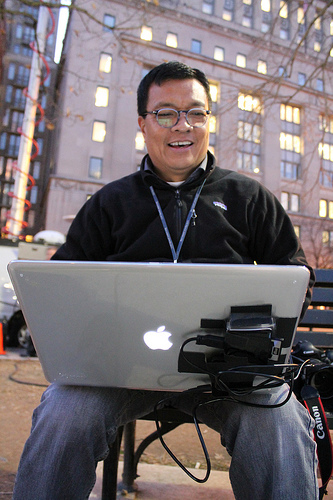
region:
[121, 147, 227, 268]
Blue lanyard in the neck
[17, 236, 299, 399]
Macbook on the man's lap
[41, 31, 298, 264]
A man wearing black fleece pullover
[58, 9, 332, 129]
Commercial building behind the man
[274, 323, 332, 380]
Canon Camara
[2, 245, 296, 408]
Apple laptop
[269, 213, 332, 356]
Black bench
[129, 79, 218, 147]
a man wearing prescription glasses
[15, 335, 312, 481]
A man wearing a blue jeans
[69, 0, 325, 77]
Leafless tree branches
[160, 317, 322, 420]
wires for man's computer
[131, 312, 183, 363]
computer makers logo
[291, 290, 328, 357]
bench man is sitting on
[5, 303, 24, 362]
car tire behind the man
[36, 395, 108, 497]
denim jean leg of man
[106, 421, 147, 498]
legs of the bench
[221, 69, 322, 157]
tree branches in background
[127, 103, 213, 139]
glasses on the man's face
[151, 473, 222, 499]
shadow on the ground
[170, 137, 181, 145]
gap in man's teeth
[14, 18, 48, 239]
red spiraled cord on antenna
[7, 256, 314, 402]
an Apple laptop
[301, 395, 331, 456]
a red and black camera strap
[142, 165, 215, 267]
a blue lanyard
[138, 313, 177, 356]
the Apple logo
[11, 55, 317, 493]
a man on a park bench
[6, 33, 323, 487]
a man outside on his computer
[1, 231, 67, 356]
a TV van parked behind the man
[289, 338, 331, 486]
camera on the bench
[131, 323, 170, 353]
Apple log on laptop computer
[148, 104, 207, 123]
glasses on the man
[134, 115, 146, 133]
ear on the man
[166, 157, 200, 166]
chin on the man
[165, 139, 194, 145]
teeth on the man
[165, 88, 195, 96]
forehead on the man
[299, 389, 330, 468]
a canon black strap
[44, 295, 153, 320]
portion of cover on compter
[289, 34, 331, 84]
branches on the tree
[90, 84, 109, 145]
windows in the building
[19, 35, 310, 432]
man holding a macbook laptop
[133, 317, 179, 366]
white backlit apple logo on a silver laptop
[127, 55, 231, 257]
man wearing a blue lanyard around his neck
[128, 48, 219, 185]
man wearing black and white glasses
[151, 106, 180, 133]
reflection of a laptop screen in glasses lens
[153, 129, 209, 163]
mouth of a smiling man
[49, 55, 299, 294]
man wearing a black zip up jacket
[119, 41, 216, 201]
man with short black hair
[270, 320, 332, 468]
Canon camera with a camera strap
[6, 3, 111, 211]
tall buildings in the background